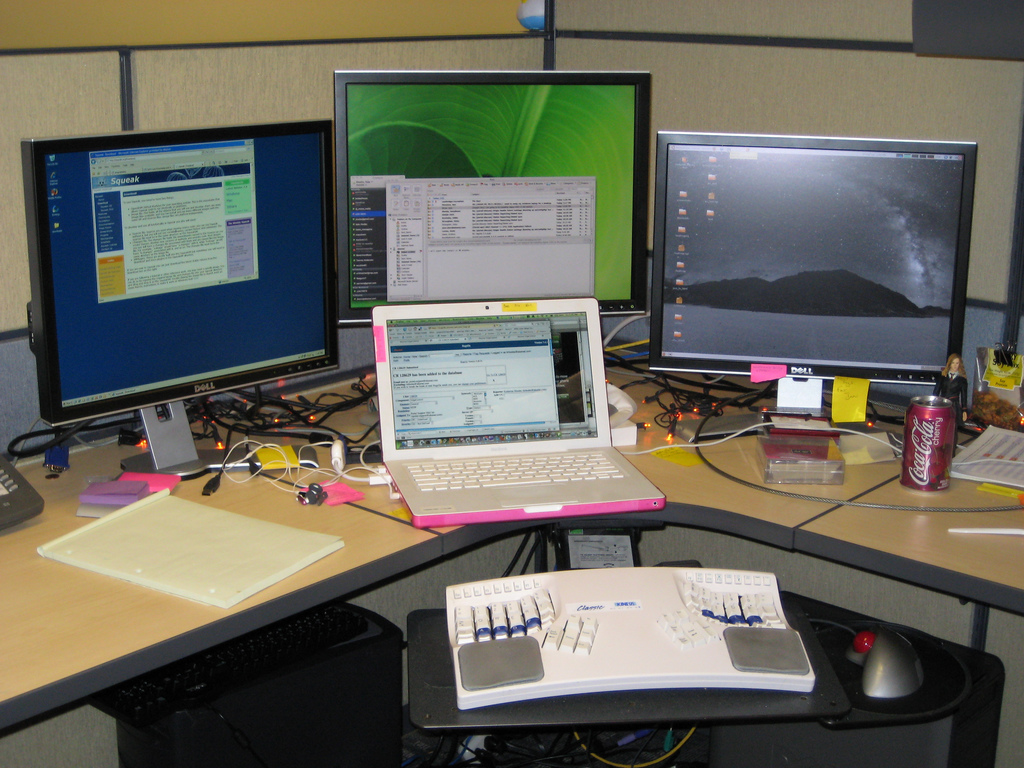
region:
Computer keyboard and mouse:
[386, 568, 1001, 755]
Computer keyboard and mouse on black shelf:
[390, 564, 992, 748]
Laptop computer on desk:
[337, 272, 702, 548]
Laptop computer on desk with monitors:
[19, 38, 996, 569]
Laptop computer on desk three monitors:
[4, 54, 1014, 558]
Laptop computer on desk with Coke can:
[352, 264, 1013, 562]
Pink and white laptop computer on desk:
[348, 278, 712, 551]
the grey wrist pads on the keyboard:
[459, 636, 548, 690]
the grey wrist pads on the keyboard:
[724, 611, 805, 681]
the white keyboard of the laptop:
[408, 443, 624, 492]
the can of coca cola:
[902, 392, 959, 488]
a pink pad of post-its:
[117, 465, 188, 497]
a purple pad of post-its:
[80, 477, 148, 503]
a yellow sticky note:
[832, 373, 872, 422]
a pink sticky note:
[746, 361, 791, 382]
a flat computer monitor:
[20, 117, 346, 415]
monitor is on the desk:
[18, 111, 344, 489]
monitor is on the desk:
[648, 119, 981, 449]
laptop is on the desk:
[370, 292, 669, 537]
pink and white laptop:
[382, 290, 648, 531]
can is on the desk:
[878, 391, 971, 508]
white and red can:
[900, 384, 959, 499]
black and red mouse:
[843, 618, 936, 707]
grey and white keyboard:
[435, 545, 822, 710]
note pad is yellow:
[49, 485, 337, 634]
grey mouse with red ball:
[833, 619, 935, 711]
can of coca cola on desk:
[897, 385, 965, 497]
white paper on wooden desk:
[31, 471, 351, 620]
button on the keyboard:
[506, 593, 539, 629]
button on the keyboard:
[729, 603, 748, 617]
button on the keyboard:
[588, 628, 590, 649]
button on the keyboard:
[565, 628, 572, 654]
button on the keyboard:
[575, 658, 596, 700]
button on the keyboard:
[571, 466, 581, 483]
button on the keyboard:
[481, 429, 517, 496]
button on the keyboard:
[505, 467, 512, 471]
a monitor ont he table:
[663, 64, 1002, 363]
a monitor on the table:
[296, 21, 652, 323]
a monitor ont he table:
[97, 91, 274, 376]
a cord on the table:
[272, 372, 304, 434]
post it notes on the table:
[219, 434, 277, 472]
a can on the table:
[898, 388, 937, 478]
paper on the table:
[80, 444, 347, 675]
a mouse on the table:
[816, 624, 947, 713]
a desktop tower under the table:
[158, 586, 371, 763]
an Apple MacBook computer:
[368, 294, 663, 528]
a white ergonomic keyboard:
[444, 562, 817, 709]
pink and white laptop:
[356, 279, 673, 535]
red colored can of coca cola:
[890, 377, 963, 507]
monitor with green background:
[331, 62, 660, 320]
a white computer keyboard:
[412, 567, 817, 704]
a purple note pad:
[74, 466, 154, 517]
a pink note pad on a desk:
[300, 478, 358, 510]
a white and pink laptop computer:
[357, 294, 668, 538]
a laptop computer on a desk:
[376, 308, 680, 543]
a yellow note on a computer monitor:
[826, 373, 877, 427]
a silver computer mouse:
[852, 620, 944, 706]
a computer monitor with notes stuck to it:
[652, 125, 953, 398]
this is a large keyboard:
[442, 553, 803, 713]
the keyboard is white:
[471, 553, 912, 762]